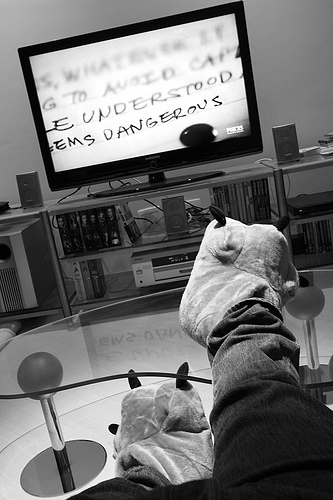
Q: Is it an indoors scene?
A: Yes, it is indoors.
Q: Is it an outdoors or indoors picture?
A: It is indoors.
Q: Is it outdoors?
A: No, it is indoors.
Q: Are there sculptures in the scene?
A: No, there are no sculptures.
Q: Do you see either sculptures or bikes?
A: No, there are no sculptures or bikes.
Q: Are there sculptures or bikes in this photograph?
A: No, there are no sculptures or bikes.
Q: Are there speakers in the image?
A: Yes, there is a speaker.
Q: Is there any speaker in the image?
A: Yes, there is a speaker.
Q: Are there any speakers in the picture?
A: Yes, there is a speaker.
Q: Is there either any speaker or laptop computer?
A: Yes, there is a speaker.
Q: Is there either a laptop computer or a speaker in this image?
A: Yes, there is a speaker.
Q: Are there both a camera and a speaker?
A: No, there is a speaker but no cameras.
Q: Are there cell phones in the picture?
A: No, there are no cell phones.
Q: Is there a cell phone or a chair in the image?
A: No, there are no cell phones or chairs.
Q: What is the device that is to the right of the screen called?
A: The device is a speaker.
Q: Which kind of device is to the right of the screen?
A: The device is a speaker.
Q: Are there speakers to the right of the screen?
A: Yes, there is a speaker to the right of the screen.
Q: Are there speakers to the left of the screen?
A: No, the speaker is to the right of the screen.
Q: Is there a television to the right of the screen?
A: No, there is a speaker to the right of the screen.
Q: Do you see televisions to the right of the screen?
A: No, there is a speaker to the right of the screen.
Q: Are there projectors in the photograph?
A: No, there are no projectors.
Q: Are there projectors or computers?
A: No, there are no projectors or computers.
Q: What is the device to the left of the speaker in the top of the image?
A: The device is a screen.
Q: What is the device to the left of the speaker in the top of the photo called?
A: The device is a screen.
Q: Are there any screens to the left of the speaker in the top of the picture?
A: Yes, there is a screen to the left of the speaker.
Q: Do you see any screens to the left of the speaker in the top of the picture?
A: Yes, there is a screen to the left of the speaker.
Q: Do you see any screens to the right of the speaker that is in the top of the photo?
A: No, the screen is to the left of the speaker.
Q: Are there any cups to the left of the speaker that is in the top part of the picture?
A: No, there is a screen to the left of the speaker.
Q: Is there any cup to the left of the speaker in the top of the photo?
A: No, there is a screen to the left of the speaker.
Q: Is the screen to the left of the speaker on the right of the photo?
A: Yes, the screen is to the left of the speaker.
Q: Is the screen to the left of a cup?
A: No, the screen is to the left of the speaker.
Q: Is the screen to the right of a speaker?
A: No, the screen is to the left of a speaker.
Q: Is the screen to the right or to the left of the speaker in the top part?
A: The screen is to the left of the speaker.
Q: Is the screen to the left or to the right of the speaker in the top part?
A: The screen is to the left of the speaker.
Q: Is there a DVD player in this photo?
A: Yes, there is a DVD player.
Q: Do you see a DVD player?
A: Yes, there is a DVD player.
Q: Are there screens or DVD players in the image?
A: Yes, there is a DVD player.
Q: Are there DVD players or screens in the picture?
A: Yes, there is a DVD player.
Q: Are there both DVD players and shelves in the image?
A: Yes, there are both a DVD player and a shelf.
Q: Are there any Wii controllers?
A: No, there are no Wii controllers.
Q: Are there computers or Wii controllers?
A: No, there are no Wii controllers or computers.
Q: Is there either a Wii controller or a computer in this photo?
A: No, there are no Wii controllers or computers.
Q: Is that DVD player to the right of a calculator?
A: No, the DVD player is to the right of the speaker.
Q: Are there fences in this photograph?
A: No, there are no fences.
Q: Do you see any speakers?
A: Yes, there is a speaker.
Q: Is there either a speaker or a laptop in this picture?
A: Yes, there is a speaker.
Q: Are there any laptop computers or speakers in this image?
A: Yes, there is a speaker.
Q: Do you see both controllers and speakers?
A: No, there is a speaker but no controllers.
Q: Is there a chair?
A: No, there are no chairs.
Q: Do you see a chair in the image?
A: No, there are no chairs.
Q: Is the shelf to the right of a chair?
A: No, the shelf is to the right of the speaker.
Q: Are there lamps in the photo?
A: No, there are no lamps.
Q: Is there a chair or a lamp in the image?
A: No, there are no lamps or chairs.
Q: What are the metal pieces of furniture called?
A: The pieces of furniture are shelves.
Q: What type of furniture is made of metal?
A: The furniture is shelves.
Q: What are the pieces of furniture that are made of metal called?
A: The pieces of furniture are shelves.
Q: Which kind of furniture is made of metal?
A: The furniture is shelves.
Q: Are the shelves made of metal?
A: Yes, the shelves are made of metal.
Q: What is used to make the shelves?
A: The shelves are made of metal.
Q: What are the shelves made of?
A: The shelves are made of metal.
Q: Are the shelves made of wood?
A: No, the shelves are made of metal.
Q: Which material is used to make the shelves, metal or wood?
A: The shelves are made of metal.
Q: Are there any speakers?
A: Yes, there is a speaker.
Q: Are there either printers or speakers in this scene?
A: Yes, there is a speaker.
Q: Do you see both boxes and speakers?
A: No, there is a speaker but no boxes.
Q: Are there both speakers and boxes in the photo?
A: No, there is a speaker but no boxes.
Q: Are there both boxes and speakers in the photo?
A: No, there is a speaker but no boxes.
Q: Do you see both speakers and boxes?
A: No, there is a speaker but no boxes.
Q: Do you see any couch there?
A: No, there are no couches.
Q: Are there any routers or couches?
A: No, there are no couches or routers.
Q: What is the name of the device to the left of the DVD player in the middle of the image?
A: The device is a speaker.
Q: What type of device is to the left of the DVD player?
A: The device is a speaker.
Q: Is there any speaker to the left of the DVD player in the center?
A: Yes, there is a speaker to the left of the DVD player.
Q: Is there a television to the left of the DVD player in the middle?
A: No, there is a speaker to the left of the DVD player.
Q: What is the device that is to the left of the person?
A: The device is a speaker.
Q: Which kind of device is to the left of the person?
A: The device is a speaker.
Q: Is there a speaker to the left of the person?
A: Yes, there is a speaker to the left of the person.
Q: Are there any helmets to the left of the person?
A: No, there is a speaker to the left of the person.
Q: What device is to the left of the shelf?
A: The device is a speaker.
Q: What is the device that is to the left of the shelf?
A: The device is a speaker.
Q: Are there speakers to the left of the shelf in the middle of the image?
A: Yes, there is a speaker to the left of the shelf.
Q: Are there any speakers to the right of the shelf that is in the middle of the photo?
A: No, the speaker is to the left of the shelf.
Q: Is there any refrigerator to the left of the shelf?
A: No, there is a speaker to the left of the shelf.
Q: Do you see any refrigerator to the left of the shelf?
A: No, there is a speaker to the left of the shelf.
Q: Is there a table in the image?
A: Yes, there is a table.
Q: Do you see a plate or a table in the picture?
A: Yes, there is a table.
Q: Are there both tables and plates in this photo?
A: No, there is a table but no plates.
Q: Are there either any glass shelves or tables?
A: Yes, there is a glass table.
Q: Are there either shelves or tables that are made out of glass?
A: Yes, the table is made of glass.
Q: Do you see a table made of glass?
A: Yes, there is a table that is made of glass.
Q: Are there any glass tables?
A: Yes, there is a table that is made of glass.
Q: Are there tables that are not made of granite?
A: Yes, there is a table that is made of glass.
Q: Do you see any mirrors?
A: No, there are no mirrors.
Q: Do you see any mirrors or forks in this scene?
A: No, there are no mirrors or forks.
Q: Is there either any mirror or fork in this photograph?
A: No, there are no mirrors or forks.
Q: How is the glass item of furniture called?
A: The piece of furniture is a table.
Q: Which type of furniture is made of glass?
A: The furniture is a table.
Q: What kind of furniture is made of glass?
A: The furniture is a table.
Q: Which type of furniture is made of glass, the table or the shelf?
A: The table is made of glass.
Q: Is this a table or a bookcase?
A: This is a table.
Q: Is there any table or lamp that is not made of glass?
A: No, there is a table but it is made of glass.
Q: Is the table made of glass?
A: Yes, the table is made of glass.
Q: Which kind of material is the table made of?
A: The table is made of glass.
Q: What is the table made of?
A: The table is made of glass.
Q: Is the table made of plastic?
A: No, the table is made of glass.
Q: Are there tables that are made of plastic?
A: No, there is a table but it is made of glass.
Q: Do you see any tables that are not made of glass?
A: No, there is a table but it is made of glass.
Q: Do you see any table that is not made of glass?
A: No, there is a table but it is made of glass.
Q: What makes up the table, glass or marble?
A: The table is made of glass.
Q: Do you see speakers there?
A: Yes, there is a speaker.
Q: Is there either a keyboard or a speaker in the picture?
A: Yes, there is a speaker.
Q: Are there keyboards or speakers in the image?
A: Yes, there is a speaker.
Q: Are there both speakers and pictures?
A: No, there is a speaker but no pictures.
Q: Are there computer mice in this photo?
A: No, there are no computer mice.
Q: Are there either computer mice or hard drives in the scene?
A: No, there are no computer mice or hard drives.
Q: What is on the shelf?
A: The speaker is on the shelf.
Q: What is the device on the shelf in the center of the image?
A: The device is a speaker.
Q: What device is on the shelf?
A: The device is a speaker.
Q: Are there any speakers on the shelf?
A: Yes, there is a speaker on the shelf.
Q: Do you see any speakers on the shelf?
A: Yes, there is a speaker on the shelf.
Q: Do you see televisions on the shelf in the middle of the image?
A: No, there is a speaker on the shelf.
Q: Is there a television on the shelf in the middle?
A: No, there is a speaker on the shelf.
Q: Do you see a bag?
A: No, there are no bags.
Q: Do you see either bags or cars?
A: No, there are no bags or cars.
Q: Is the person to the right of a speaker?
A: Yes, the person is to the right of a speaker.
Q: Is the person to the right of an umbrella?
A: No, the person is to the right of a speaker.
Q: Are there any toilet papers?
A: No, there are no toilet papers.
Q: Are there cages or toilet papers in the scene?
A: No, there are no toilet papers or cages.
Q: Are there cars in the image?
A: No, there are no cars.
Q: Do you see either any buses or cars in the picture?
A: No, there are no cars or buses.